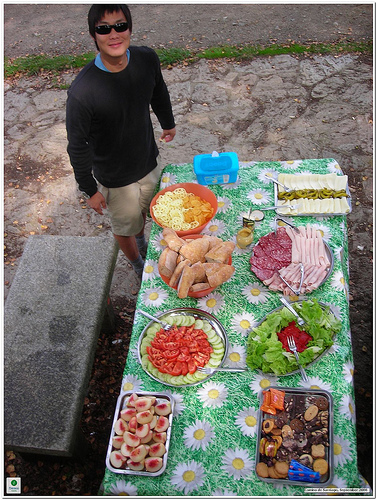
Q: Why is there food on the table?
A: Mealtime.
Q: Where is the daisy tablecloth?
A: Under the food.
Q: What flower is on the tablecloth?
A: Daisy.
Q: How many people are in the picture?
A: One.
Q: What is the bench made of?
A: Concrete.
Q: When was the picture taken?
A: Daytime.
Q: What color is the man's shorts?
A: Khaki.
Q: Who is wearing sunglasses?
A: The man.